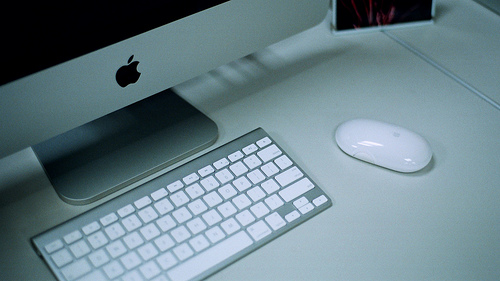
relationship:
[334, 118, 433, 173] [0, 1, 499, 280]
mouse on desk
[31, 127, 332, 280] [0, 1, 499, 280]
keyboard on desk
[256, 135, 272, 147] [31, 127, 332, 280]
button on keyboard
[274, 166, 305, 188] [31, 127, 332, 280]
button on keyboard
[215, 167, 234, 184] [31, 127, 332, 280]
button on keyboard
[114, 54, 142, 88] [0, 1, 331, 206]
apple on computer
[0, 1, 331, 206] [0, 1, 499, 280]
computer on desk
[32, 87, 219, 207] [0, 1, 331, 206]
leg on computer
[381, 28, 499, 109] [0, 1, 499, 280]
cord on desk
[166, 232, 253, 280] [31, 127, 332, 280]
space bar on keyboard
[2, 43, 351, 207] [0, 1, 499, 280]
shadow on desk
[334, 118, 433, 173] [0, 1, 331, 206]
mouse for computer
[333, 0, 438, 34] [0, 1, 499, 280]
card on top of desk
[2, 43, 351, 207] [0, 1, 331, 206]
shadow cast by computer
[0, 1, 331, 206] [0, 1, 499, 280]
computer sitting on desk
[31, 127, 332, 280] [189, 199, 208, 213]
keyboard has key